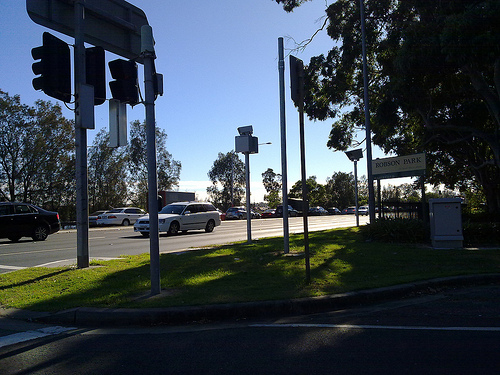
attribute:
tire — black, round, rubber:
[27, 222, 49, 244]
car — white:
[135, 199, 223, 240]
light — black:
[26, 30, 72, 105]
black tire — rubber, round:
[122, 217, 128, 224]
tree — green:
[319, 21, 485, 196]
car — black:
[0, 195, 64, 245]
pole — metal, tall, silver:
[354, 1, 381, 226]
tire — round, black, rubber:
[170, 220, 180, 235]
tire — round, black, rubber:
[206, 220, 216, 232]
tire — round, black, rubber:
[28, 222, 50, 239]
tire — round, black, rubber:
[119, 217, 131, 225]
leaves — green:
[312, 36, 369, 121]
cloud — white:
[123, 179, 327, 200]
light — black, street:
[28, 31, 71, 107]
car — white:
[143, 198, 225, 234]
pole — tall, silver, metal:
[276, 37, 293, 249]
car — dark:
[4, 180, 69, 270]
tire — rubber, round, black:
[205, 215, 216, 231]